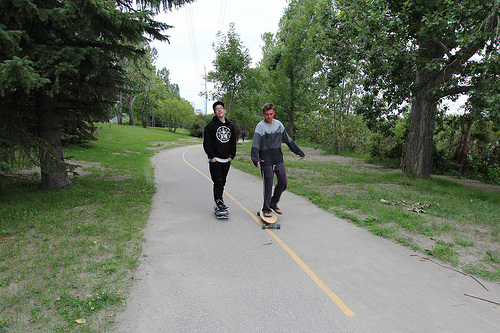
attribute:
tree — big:
[3, 0, 158, 202]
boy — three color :
[258, 93, 311, 210]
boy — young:
[250, 102, 305, 218]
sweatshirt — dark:
[204, 112, 249, 164]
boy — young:
[248, 97, 286, 220]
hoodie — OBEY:
[198, 114, 270, 186]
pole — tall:
[203, 62, 208, 113]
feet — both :
[258, 202, 273, 219]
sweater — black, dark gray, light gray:
[249, 118, 302, 160]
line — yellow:
[183, 145, 354, 331]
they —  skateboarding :
[248, 99, 302, 219]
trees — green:
[1, 0, 498, 216]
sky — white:
[117, 1, 295, 113]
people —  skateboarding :
[203, 93, 305, 223]